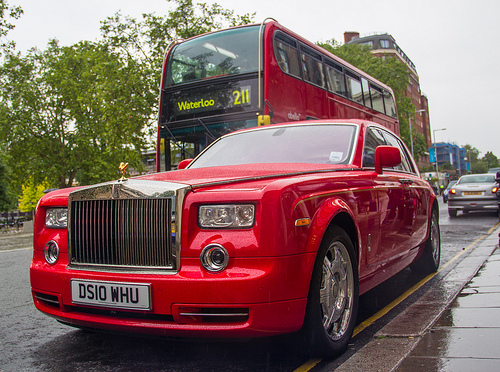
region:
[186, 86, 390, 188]
the windshield on a car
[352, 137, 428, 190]
the mirror on a car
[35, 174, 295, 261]
the headlights on a car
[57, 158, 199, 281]
the grill on a car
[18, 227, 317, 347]
the bumper on a car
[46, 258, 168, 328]
the license plate on a car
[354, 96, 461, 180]
the side window on a car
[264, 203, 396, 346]
the wheel on a car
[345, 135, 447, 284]
the door on a car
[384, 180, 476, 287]
the back wheel on a car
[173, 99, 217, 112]
green "Waterloo" on bus display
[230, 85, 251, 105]
"211" written on bus display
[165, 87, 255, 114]
digital bus display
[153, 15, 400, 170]
a red and black double decker bus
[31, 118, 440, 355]
a sleek red car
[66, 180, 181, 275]
chrome grill on a car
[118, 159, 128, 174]
gold emblem on hood of car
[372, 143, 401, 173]
red driver mirror on car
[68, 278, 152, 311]
license plate on car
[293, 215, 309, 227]
orange side reflector on car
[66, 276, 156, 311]
Grey plate with black letters on front of car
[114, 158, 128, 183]
gold figure on the hood of the car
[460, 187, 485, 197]
licence plate is yellow with blue wording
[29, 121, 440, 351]
Red car with silver trim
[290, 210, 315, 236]
small yellow light on the front left side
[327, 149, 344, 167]
white square in the front window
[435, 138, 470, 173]
blue building on the left hand side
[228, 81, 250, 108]
number 211 on the front of the bus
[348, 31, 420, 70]
top floor of a building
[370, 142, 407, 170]
mirror on a car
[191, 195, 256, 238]
light on a car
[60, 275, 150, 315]
license plate on a car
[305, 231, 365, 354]
tire on a car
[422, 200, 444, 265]
tire on a car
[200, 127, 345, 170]
window on a car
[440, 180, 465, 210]
light on a car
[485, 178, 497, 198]
light on a car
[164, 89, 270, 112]
sign on a bus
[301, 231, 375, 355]
tires on the car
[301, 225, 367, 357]
wheel on the car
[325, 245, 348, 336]
rim on the tire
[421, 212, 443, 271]
wheel on the car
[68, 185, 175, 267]
grill on the car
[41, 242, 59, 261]
fog light on the car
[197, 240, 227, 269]
fog light on the car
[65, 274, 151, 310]
license plate on the car